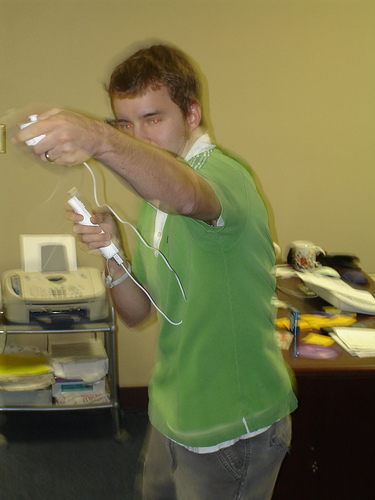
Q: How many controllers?
A: 1.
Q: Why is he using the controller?
A: To play.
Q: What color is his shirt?
A: Green.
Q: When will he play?
A: Now.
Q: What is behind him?
A: Fax machine.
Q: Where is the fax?
A: Behind him.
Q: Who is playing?
A: The guy.